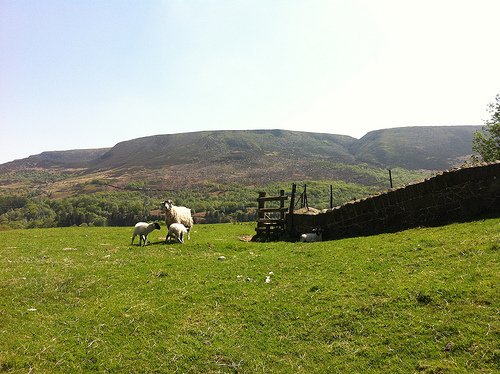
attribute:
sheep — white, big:
[157, 196, 195, 233]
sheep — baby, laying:
[162, 220, 192, 244]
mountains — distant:
[7, 123, 493, 199]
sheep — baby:
[129, 217, 162, 246]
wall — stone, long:
[249, 157, 496, 236]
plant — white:
[4, 254, 35, 287]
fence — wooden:
[250, 181, 311, 244]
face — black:
[152, 219, 163, 233]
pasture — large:
[13, 178, 332, 211]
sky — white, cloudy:
[364, 1, 496, 117]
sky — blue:
[2, 4, 306, 110]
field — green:
[6, 219, 498, 371]